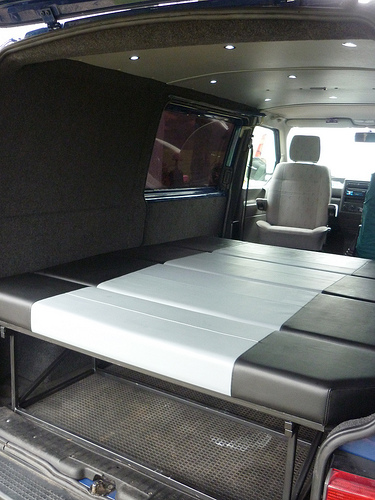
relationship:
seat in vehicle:
[253, 129, 343, 252] [1, 1, 373, 497]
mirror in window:
[347, 123, 373, 157] [291, 123, 373, 178]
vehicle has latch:
[1, 1, 373, 497] [85, 466, 120, 498]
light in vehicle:
[344, 187, 352, 197] [1, 1, 373, 497]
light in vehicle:
[223, 43, 234, 49] [1, 1, 373, 497]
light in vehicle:
[129, 54, 139, 62] [1, 1, 373, 497]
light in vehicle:
[287, 72, 297, 82] [1, 1, 373, 497]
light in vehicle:
[210, 79, 216, 85] [1, 1, 373, 497]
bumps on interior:
[21, 365, 328, 499] [14, 62, 352, 481]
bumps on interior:
[21, 365, 328, 499] [23, 364, 317, 499]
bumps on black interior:
[21, 365, 328, 499] [0, 19, 373, 499]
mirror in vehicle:
[141, 87, 249, 199] [1, 1, 373, 497]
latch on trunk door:
[34, 3, 66, 30] [1, 0, 185, 31]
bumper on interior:
[0, 452, 81, 499] [1, 0, 373, 499]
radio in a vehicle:
[344, 180, 369, 199] [1, 1, 373, 497]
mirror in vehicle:
[354, 131, 375, 142] [1, 1, 373, 497]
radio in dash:
[345, 186, 369, 198] [334, 179, 373, 217]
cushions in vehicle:
[0, 235, 375, 425] [1, 1, 373, 497]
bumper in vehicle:
[0, 452, 85, 498] [1, 1, 373, 497]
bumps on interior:
[21, 365, 328, 499] [1, 0, 373, 499]